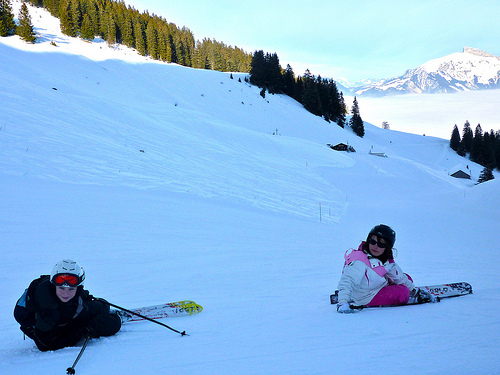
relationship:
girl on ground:
[327, 218, 484, 316] [278, 195, 401, 209]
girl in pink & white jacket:
[327, 218, 484, 316] [354, 255, 403, 309]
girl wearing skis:
[327, 218, 484, 316] [426, 283, 474, 309]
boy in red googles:
[13, 281, 143, 328] [48, 273, 84, 284]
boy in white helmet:
[13, 281, 143, 328] [36, 260, 95, 273]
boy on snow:
[13, 281, 143, 328] [106, 74, 164, 93]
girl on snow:
[327, 218, 484, 316] [106, 74, 164, 93]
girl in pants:
[327, 218, 484, 316] [364, 284, 424, 306]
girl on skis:
[327, 218, 484, 316] [426, 283, 474, 309]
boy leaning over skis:
[13, 281, 143, 328] [119, 302, 205, 324]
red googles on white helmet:
[48, 273, 84, 284] [36, 260, 95, 273]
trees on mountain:
[105, 6, 231, 66] [378, 38, 496, 93]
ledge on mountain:
[458, 48, 490, 60] [378, 38, 496, 93]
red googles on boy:
[48, 273, 84, 284] [13, 281, 143, 328]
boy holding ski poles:
[13, 281, 143, 328] [111, 293, 189, 348]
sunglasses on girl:
[364, 237, 390, 247] [327, 218, 484, 316]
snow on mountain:
[106, 74, 164, 93] [378, 38, 496, 93]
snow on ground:
[106, 74, 164, 93] [278, 195, 401, 209]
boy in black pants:
[13, 281, 143, 328] [85, 300, 121, 338]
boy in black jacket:
[13, 281, 143, 328] [35, 293, 70, 338]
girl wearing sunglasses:
[327, 218, 484, 316] [364, 237, 390, 247]